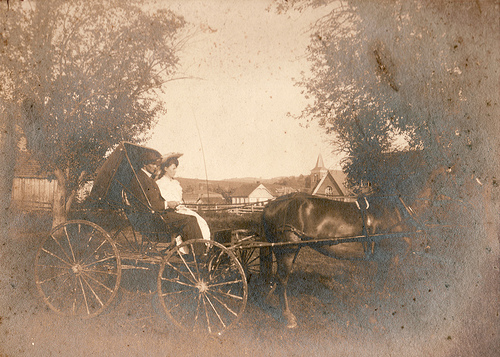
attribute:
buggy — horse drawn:
[33, 206, 248, 338]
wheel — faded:
[17, 216, 119, 312]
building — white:
[226, 180, 274, 217]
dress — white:
[155, 175, 209, 239]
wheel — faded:
[26, 215, 125, 325]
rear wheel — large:
[22, 211, 125, 324]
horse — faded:
[247, 154, 494, 334]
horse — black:
[246, 143, 498, 345]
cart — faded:
[33, 142, 251, 337]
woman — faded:
[154, 154, 212, 237]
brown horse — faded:
[254, 167, 483, 332]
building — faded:
[295, 149, 360, 202]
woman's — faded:
[162, 153, 208, 245]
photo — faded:
[5, 6, 496, 348]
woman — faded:
[151, 147, 222, 239]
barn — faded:
[189, 190, 225, 213]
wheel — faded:
[157, 237, 248, 337]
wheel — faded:
[152, 233, 256, 346]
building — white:
[229, 179, 275, 210]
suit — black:
[122, 167, 207, 255]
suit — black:
[128, 166, 209, 255]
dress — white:
[147, 172, 211, 251]